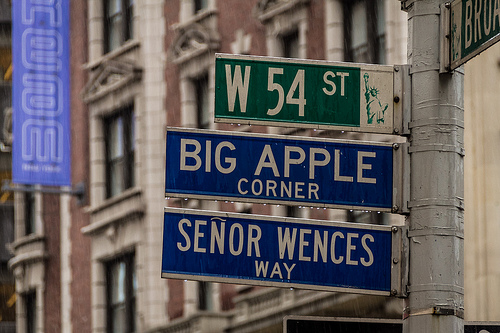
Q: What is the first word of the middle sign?
A: Big.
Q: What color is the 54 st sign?
A: Green.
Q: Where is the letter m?
A: On the banner.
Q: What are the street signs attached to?
A: Pole.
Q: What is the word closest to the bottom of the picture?
A: Way.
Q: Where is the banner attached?
A: To the building.